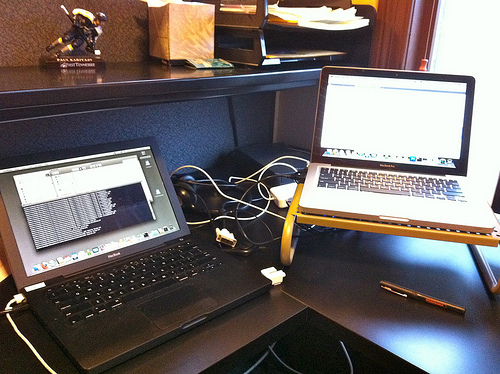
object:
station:
[0, 64, 499, 373]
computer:
[294, 65, 497, 235]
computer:
[1, 132, 276, 373]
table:
[235, 213, 500, 374]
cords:
[169, 165, 211, 178]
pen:
[376, 280, 468, 317]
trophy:
[41, 4, 109, 70]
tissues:
[148, 0, 215, 9]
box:
[144, 1, 217, 71]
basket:
[213, 0, 369, 70]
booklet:
[182, 58, 235, 70]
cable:
[166, 154, 308, 248]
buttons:
[395, 183, 404, 187]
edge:
[297, 214, 498, 248]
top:
[0, 41, 349, 99]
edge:
[299, 202, 498, 235]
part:
[326, 73, 466, 99]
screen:
[320, 72, 467, 169]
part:
[214, 223, 237, 249]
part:
[135, 281, 214, 317]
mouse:
[135, 284, 221, 330]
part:
[299, 186, 498, 231]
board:
[295, 164, 498, 233]